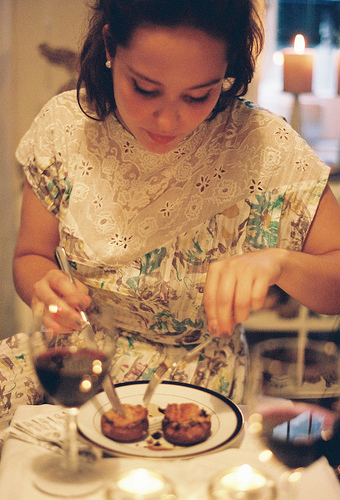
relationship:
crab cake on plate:
[162, 393, 205, 459] [56, 351, 286, 453]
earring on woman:
[103, 50, 129, 80] [6, 15, 338, 391]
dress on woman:
[12, 94, 322, 390] [6, 15, 338, 391]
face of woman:
[104, 24, 238, 151] [6, 15, 338, 391]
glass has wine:
[27, 291, 140, 491] [35, 342, 112, 389]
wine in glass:
[35, 342, 112, 389] [27, 291, 140, 491]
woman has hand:
[6, 15, 338, 391] [200, 234, 274, 339]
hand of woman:
[200, 234, 274, 339] [6, 15, 338, 391]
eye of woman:
[171, 66, 227, 109] [6, 15, 338, 391]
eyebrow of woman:
[183, 63, 228, 95] [6, 15, 338, 391]